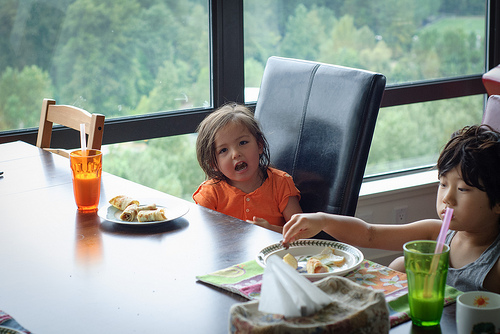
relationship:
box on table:
[225, 257, 390, 333] [0, 136, 498, 332]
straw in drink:
[77, 122, 90, 174] [63, 145, 110, 218]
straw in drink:
[421, 200, 459, 295] [393, 228, 462, 323]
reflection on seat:
[265, 110, 356, 228] [232, 38, 372, 228]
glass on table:
[399, 241, 454, 328] [1, 130, 485, 322]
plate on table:
[258, 237, 367, 281] [0, 136, 498, 332]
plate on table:
[96, 191, 192, 231] [0, 136, 498, 332]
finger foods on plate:
[107, 195, 167, 220] [86, 187, 207, 231]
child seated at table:
[196, 107, 280, 209] [0, 136, 498, 332]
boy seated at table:
[283, 124, 499, 291] [0, 136, 498, 332]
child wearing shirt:
[193, 104, 304, 236] [184, 171, 298, 237]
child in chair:
[193, 104, 304, 236] [242, 32, 397, 229]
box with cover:
[222, 257, 389, 329] [219, 262, 400, 327]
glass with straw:
[399, 241, 454, 328] [424, 205, 454, 300]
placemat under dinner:
[187, 271, 269, 294] [256, 238, 378, 281]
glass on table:
[64, 142, 105, 218] [0, 136, 498, 332]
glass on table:
[395, 224, 456, 329] [18, 114, 382, 330]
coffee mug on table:
[452, 287, 499, 332] [0, 136, 498, 332]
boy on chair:
[283, 124, 499, 291] [481, 96, 498, 131]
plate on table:
[96, 191, 188, 231] [0, 136, 498, 332]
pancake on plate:
[111, 193, 138, 206] [97, 192, 190, 229]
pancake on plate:
[118, 200, 142, 217] [97, 192, 190, 229]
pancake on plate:
[137, 205, 167, 220] [97, 192, 190, 229]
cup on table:
[400, 237, 454, 327] [0, 136, 498, 332]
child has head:
[193, 104, 304, 236] [183, 103, 280, 181]